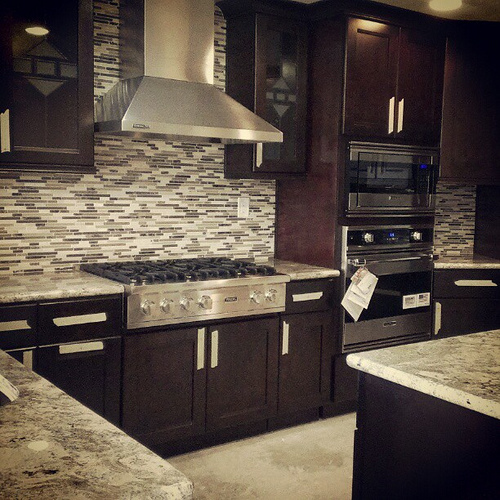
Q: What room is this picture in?
A: It is at the kitchen.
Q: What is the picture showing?
A: It is showing a kitchen.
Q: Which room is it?
A: It is a kitchen.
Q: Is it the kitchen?
A: Yes, it is the kitchen.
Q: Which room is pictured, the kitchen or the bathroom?
A: It is the kitchen.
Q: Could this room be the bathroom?
A: No, it is the kitchen.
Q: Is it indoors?
A: Yes, it is indoors.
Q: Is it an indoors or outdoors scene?
A: It is indoors.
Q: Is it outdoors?
A: No, it is indoors.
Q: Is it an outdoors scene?
A: No, it is indoors.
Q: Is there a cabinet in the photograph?
A: Yes, there is a cabinet.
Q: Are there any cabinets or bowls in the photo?
A: Yes, there is a cabinet.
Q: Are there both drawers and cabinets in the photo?
A: Yes, there are both a cabinet and drawers.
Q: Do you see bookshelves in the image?
A: No, there are no bookshelves.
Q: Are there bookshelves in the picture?
A: No, there are no bookshelves.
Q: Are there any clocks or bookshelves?
A: No, there are no bookshelves or clocks.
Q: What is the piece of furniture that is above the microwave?
A: The piece of furniture is a cabinet.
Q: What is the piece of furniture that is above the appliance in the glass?
A: The piece of furniture is a cabinet.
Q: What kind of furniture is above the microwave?
A: The piece of furniture is a cabinet.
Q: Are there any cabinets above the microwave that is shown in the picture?
A: Yes, there is a cabinet above the microwave.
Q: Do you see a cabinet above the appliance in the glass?
A: Yes, there is a cabinet above the microwave.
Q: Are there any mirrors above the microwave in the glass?
A: No, there is a cabinet above the microwave.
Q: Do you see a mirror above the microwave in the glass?
A: No, there is a cabinet above the microwave.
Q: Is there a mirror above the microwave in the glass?
A: No, there is a cabinet above the microwave.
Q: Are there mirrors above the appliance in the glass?
A: No, there is a cabinet above the microwave.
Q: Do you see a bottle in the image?
A: No, there are no bottles.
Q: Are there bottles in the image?
A: No, there are no bottles.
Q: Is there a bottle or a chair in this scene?
A: No, there are no bottles or chairs.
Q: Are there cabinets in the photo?
A: Yes, there is a cabinet.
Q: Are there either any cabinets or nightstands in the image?
A: Yes, there is a cabinet.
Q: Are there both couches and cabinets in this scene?
A: No, there is a cabinet but no couches.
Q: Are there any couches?
A: No, there are no couches.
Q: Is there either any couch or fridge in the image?
A: No, there are no couches or refrigerators.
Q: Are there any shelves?
A: No, there are no shelves.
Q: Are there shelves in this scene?
A: No, there are no shelves.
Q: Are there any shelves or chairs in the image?
A: No, there are no shelves or chairs.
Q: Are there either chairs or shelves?
A: No, there are no shelves or chairs.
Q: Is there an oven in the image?
A: Yes, there is an oven.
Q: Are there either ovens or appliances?
A: Yes, there is an oven.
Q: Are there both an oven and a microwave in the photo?
A: Yes, there are both an oven and a microwave.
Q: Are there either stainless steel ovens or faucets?
A: Yes, there is a stainless steel oven.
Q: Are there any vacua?
A: No, there are no vacua.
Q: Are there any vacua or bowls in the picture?
A: No, there are no vacua or bowls.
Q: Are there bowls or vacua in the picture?
A: No, there are no vacua or bowls.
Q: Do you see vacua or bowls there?
A: No, there are no vacua or bowls.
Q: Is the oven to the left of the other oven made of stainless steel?
A: Yes, the oven is made of stainless steel.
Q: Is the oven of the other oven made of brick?
A: No, the oven is made of stainless steel.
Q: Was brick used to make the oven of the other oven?
A: No, the oven is made of stainless steel.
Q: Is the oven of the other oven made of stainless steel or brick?
A: The oven is made of stainless steel.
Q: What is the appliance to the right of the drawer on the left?
A: The appliance is an oven.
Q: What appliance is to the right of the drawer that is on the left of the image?
A: The appliance is an oven.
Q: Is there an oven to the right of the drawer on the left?
A: Yes, there is an oven to the right of the drawer.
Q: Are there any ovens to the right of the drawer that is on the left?
A: Yes, there is an oven to the right of the drawer.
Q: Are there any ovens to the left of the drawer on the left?
A: No, the oven is to the right of the drawer.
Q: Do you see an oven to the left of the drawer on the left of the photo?
A: No, the oven is to the right of the drawer.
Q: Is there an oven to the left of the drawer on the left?
A: No, the oven is to the right of the drawer.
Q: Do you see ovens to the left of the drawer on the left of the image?
A: No, the oven is to the right of the drawer.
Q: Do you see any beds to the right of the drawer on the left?
A: No, there is an oven to the right of the drawer.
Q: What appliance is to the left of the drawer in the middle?
A: The appliance is an oven.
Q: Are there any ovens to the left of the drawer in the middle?
A: Yes, there is an oven to the left of the drawer.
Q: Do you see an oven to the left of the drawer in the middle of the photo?
A: Yes, there is an oven to the left of the drawer.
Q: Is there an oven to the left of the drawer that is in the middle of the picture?
A: Yes, there is an oven to the left of the drawer.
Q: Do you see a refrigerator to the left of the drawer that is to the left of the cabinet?
A: No, there is an oven to the left of the drawer.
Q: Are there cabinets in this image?
A: Yes, there is a cabinet.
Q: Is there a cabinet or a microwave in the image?
A: Yes, there is a cabinet.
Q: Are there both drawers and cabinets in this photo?
A: Yes, there are both a cabinet and a drawer.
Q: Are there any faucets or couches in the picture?
A: No, there are no faucets or couches.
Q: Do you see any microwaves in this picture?
A: Yes, there is a microwave.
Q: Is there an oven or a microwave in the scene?
A: Yes, there is a microwave.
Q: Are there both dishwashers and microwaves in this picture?
A: No, there is a microwave but no dishwashers.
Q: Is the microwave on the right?
A: Yes, the microwave is on the right of the image.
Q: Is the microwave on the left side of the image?
A: No, the microwave is on the right of the image.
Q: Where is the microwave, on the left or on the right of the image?
A: The microwave is on the right of the image.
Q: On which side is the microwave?
A: The microwave is on the right of the image.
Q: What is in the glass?
A: The microwave is in the glass.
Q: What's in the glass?
A: The microwave is in the glass.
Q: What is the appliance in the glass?
A: The appliance is a microwave.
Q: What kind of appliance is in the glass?
A: The appliance is a microwave.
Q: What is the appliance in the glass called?
A: The appliance is a microwave.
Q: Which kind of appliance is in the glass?
A: The appliance is a microwave.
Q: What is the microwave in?
A: The microwave is in the glass.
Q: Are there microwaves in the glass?
A: Yes, there is a microwave in the glass.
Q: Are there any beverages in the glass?
A: No, there is a microwave in the glass.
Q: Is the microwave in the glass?
A: Yes, the microwave is in the glass.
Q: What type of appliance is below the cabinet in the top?
A: The appliance is a microwave.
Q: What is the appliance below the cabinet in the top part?
A: The appliance is a microwave.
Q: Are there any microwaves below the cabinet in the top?
A: Yes, there is a microwave below the cabinet.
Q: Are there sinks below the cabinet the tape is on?
A: No, there is a microwave below the cabinet.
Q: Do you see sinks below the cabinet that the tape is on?
A: No, there is a microwave below the cabinet.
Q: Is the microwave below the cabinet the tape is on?
A: Yes, the microwave is below the cabinet.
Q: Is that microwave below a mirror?
A: No, the microwave is below the cabinet.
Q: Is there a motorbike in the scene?
A: No, there are no motorcycles.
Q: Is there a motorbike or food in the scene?
A: No, there are no motorcycles or food.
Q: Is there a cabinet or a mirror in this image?
A: Yes, there is a cabinet.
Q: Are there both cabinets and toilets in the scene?
A: No, there is a cabinet but no toilets.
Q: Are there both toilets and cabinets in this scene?
A: No, there is a cabinet but no toilets.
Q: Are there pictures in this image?
A: No, there are no pictures.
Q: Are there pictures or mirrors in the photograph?
A: No, there are no pictures or mirrors.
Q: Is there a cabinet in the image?
A: Yes, there is a cabinet.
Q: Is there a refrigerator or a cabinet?
A: Yes, there is a cabinet.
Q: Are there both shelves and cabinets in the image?
A: No, there is a cabinet but no shelves.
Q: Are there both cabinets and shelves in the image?
A: No, there is a cabinet but no shelves.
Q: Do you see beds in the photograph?
A: No, there are no beds.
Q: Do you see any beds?
A: No, there are no beds.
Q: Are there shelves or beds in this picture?
A: No, there are no beds or shelves.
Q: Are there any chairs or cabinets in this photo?
A: Yes, there is a cabinet.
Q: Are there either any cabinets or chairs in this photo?
A: Yes, there is a cabinet.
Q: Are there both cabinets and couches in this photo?
A: No, there is a cabinet but no couches.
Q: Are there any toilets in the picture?
A: No, there are no toilets.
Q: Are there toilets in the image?
A: No, there are no toilets.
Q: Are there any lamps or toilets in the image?
A: No, there are no toilets or lamps.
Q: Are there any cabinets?
A: Yes, there is a cabinet.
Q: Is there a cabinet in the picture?
A: Yes, there is a cabinet.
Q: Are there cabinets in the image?
A: Yes, there is a cabinet.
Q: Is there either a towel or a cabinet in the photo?
A: Yes, there is a cabinet.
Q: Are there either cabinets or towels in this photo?
A: Yes, there is a cabinet.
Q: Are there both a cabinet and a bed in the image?
A: No, there is a cabinet but no beds.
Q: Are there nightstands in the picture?
A: No, there are no nightstands.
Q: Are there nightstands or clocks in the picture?
A: No, there are no nightstands or clocks.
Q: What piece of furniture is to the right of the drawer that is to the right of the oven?
A: The piece of furniture is a cabinet.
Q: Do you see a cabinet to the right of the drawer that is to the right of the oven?
A: Yes, there is a cabinet to the right of the drawer.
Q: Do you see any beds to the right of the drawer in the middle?
A: No, there is a cabinet to the right of the drawer.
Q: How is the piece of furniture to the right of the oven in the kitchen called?
A: The piece of furniture is a cabinet.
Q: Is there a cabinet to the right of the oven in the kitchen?
A: Yes, there is a cabinet to the right of the oven.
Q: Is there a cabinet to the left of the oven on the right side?
A: No, the cabinet is to the right of the oven.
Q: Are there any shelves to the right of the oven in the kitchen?
A: No, there is a cabinet to the right of the oven.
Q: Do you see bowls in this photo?
A: No, there are no bowls.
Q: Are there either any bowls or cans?
A: No, there are no bowls or cans.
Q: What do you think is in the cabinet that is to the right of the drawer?
A: The tape is in the cabinet.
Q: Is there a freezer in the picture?
A: No, there are no refrigerators.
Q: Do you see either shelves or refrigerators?
A: No, there are no refrigerators or shelves.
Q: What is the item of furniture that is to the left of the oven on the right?
A: The piece of furniture is a drawer.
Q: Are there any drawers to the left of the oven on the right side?
A: Yes, there is a drawer to the left of the oven.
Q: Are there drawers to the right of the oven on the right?
A: No, the drawer is to the left of the oven.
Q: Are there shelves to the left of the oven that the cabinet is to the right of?
A: No, there is a drawer to the left of the oven.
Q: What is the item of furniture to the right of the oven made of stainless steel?
A: The piece of furniture is a drawer.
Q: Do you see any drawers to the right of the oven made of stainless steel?
A: Yes, there is a drawer to the right of the oven.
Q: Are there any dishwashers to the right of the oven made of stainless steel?
A: No, there is a drawer to the right of the oven.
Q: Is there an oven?
A: Yes, there is an oven.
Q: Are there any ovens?
A: Yes, there is an oven.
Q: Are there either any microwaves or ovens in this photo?
A: Yes, there is an oven.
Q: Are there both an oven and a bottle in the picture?
A: No, there is an oven but no bottles.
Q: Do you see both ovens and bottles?
A: No, there is an oven but no bottles.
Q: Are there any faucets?
A: No, there are no faucets.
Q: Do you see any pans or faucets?
A: No, there are no faucets or pans.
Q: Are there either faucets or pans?
A: No, there are no faucets or pans.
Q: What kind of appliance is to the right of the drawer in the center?
A: The appliance is an oven.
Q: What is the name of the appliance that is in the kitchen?
A: The appliance is an oven.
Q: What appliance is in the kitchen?
A: The appliance is an oven.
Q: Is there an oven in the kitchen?
A: Yes, there is an oven in the kitchen.